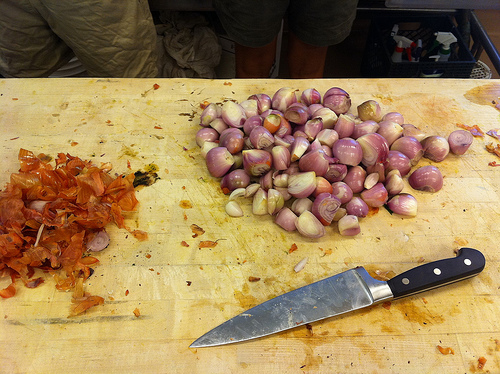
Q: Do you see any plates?
A: No, there are no plates.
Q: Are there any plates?
A: No, there are no plates.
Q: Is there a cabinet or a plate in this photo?
A: No, there are no plates or cabinets.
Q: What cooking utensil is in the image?
A: The cooking utensil is a cutting board.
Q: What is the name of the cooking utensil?
A: The cooking utensil is a cutting board.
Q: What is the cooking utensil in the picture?
A: The cooking utensil is a cutting board.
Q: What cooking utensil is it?
A: The cooking utensil is a cutting board.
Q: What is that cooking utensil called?
A: This is a cutting board.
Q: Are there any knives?
A: Yes, there is a knife.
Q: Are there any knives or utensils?
A: Yes, there is a knife.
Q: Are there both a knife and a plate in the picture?
A: No, there is a knife but no plates.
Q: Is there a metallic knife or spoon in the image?
A: Yes, there is a metal knife.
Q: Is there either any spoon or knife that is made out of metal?
A: Yes, the knife is made of metal.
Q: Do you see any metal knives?
A: Yes, there is a knife that is made of metal.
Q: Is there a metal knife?
A: Yes, there is a knife that is made of metal.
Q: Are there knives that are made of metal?
A: Yes, there is a knife that is made of metal.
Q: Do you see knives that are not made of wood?
A: Yes, there is a knife that is made of metal.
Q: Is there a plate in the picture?
A: No, there are no plates.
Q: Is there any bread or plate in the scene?
A: No, there are no plates or breads.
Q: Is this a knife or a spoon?
A: This is a knife.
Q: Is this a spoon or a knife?
A: This is a knife.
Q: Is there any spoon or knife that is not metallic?
A: No, there is a knife but it is metallic.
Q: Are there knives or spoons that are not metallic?
A: No, there is a knife but it is metallic.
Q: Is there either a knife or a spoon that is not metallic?
A: No, there is a knife but it is metallic.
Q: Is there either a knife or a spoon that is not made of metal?
A: No, there is a knife but it is made of metal.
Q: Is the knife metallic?
A: Yes, the knife is metallic.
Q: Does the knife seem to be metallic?
A: Yes, the knife is metallic.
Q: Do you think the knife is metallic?
A: Yes, the knife is metallic.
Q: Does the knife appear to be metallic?
A: Yes, the knife is metallic.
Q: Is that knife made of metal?
A: Yes, the knife is made of metal.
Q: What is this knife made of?
A: The knife is made of metal.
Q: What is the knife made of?
A: The knife is made of metal.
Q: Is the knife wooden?
A: No, the knife is metallic.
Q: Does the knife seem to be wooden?
A: No, the knife is metallic.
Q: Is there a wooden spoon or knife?
A: No, there is a knife but it is metallic.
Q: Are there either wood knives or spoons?
A: No, there is a knife but it is metallic.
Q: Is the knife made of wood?
A: No, the knife is made of metal.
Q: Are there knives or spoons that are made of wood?
A: No, there is a knife but it is made of metal.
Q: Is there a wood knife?
A: No, there is a knife but it is made of metal.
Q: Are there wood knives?
A: No, there is a knife but it is made of metal.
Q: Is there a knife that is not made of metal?
A: No, there is a knife but it is made of metal.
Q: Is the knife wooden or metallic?
A: The knife is metallic.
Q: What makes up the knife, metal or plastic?
A: The knife is made of metal.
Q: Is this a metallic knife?
A: Yes, this is a metallic knife.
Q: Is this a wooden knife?
A: No, this is a metallic knife.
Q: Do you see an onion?
A: Yes, there is an onion.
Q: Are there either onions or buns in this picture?
A: Yes, there is an onion.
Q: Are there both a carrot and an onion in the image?
A: No, there is an onion but no carrots.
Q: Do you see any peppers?
A: No, there are no peppers.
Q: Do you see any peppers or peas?
A: No, there are no peppers or peas.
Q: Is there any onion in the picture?
A: Yes, there is an onion.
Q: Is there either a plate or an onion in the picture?
A: Yes, there is an onion.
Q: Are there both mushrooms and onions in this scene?
A: No, there is an onion but no mushrooms.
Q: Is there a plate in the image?
A: No, there are no plates.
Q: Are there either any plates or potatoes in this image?
A: No, there are no plates or potatoes.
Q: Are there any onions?
A: Yes, there is an onion.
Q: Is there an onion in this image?
A: Yes, there is an onion.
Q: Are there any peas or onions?
A: Yes, there is an onion.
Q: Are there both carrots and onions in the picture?
A: No, there is an onion but no carrots.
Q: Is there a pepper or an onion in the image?
A: Yes, there is an onion.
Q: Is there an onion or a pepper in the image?
A: Yes, there is an onion.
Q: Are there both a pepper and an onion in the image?
A: No, there is an onion but no peppers.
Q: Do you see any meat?
A: No, there is no meat.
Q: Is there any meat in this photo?
A: No, there is no meat.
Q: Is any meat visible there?
A: No, there is no meat.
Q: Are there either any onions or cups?
A: Yes, there is an onion.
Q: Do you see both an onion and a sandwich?
A: No, there is an onion but no sandwiches.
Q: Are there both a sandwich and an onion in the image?
A: No, there is an onion but no sandwiches.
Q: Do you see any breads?
A: No, there are no breads.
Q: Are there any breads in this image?
A: No, there are no breads.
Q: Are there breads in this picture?
A: No, there are no breads.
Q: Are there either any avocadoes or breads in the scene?
A: No, there are no breads or avocadoes.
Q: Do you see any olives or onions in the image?
A: Yes, there are onions.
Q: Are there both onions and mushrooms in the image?
A: No, there are onions but no mushrooms.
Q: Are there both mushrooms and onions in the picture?
A: No, there are onions but no mushrooms.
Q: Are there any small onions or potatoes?
A: Yes, there are small onions.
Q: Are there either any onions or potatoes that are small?
A: Yes, the onions are small.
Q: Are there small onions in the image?
A: Yes, there are small onions.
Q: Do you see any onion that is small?
A: Yes, there are onions that are small.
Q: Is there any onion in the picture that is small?
A: Yes, there are onions that are small.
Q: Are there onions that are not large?
A: Yes, there are small onions.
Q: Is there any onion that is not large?
A: Yes, there are small onions.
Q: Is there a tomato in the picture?
A: No, there are no tomatoes.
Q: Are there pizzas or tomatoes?
A: No, there are no tomatoes or pizzas.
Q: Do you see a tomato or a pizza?
A: No, there are no tomatoes or pizzas.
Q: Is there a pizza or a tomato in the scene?
A: No, there are no tomatoes or pizzas.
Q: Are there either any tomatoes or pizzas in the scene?
A: No, there are no tomatoes or pizzas.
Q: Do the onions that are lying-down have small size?
A: Yes, the onions are small.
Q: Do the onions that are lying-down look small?
A: Yes, the onions are small.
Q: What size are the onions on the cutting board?
A: The onions are small.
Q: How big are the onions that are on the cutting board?
A: The onions are small.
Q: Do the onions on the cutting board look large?
A: No, the onions are small.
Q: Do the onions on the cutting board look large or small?
A: The onions are small.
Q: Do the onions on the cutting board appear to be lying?
A: Yes, the onions are lying.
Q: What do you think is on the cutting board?
A: The onions are on the cutting board.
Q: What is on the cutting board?
A: The onions are on the cutting board.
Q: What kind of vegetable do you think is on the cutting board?
A: The vegetables are onions.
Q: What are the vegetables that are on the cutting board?
A: The vegetables are onions.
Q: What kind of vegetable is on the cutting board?
A: The vegetables are onions.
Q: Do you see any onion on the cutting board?
A: Yes, there are onions on the cutting board.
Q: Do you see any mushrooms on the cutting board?
A: No, there are onions on the cutting board.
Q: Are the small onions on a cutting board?
A: Yes, the onions are on a cutting board.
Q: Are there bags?
A: No, there are no bags.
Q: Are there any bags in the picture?
A: No, there are no bags.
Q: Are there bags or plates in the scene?
A: No, there are no bags or plates.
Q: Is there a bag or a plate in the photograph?
A: No, there are no bags or plates.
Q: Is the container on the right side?
A: Yes, the container is on the right of the image.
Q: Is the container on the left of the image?
A: No, the container is on the right of the image.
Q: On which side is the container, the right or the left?
A: The container is on the right of the image.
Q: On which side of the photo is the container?
A: The container is on the right of the image.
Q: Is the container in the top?
A: Yes, the container is in the top of the image.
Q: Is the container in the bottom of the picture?
A: No, the container is in the top of the image.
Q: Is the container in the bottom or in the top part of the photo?
A: The container is in the top of the image.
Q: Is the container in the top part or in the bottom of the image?
A: The container is in the top of the image.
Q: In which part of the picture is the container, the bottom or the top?
A: The container is in the top of the image.